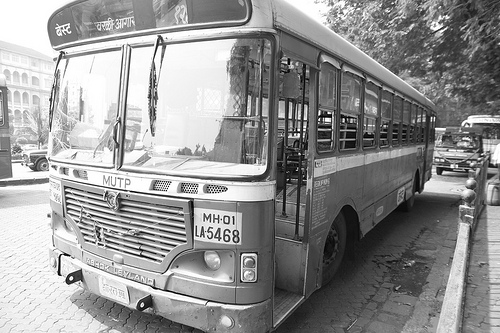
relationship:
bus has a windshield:
[48, 0, 435, 331] [46, 32, 278, 179]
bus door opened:
[44, 0, 435, 333] [269, 95, 313, 216]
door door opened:
[269, 43, 321, 326] [269, 95, 313, 216]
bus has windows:
[48, 0, 435, 331] [317, 50, 424, 146]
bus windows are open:
[48, 0, 435, 331] [279, 60, 310, 260]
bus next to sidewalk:
[48, 0, 435, 331] [409, 192, 478, 321]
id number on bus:
[193, 208, 242, 246] [48, 0, 435, 331]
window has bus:
[337, 58, 360, 158] [48, 0, 435, 331]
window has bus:
[310, 50, 335, 157] [48, 0, 435, 331]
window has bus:
[360, 67, 381, 153] [48, 0, 435, 331]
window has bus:
[380, 82, 393, 152] [48, 0, 435, 331]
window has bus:
[392, 87, 402, 149] [48, 0, 435, 331]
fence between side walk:
[454, 146, 483, 236] [408, 102, 499, 331]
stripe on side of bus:
[304, 138, 433, 177] [161, 25, 393, 302]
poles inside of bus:
[280, 97, 302, 246] [116, 13, 454, 233]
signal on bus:
[235, 246, 262, 291] [48, 0, 435, 331]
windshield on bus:
[50, 37, 270, 169] [22, 6, 467, 331]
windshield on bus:
[48, 36, 273, 177] [48, 0, 435, 331]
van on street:
[433, 127, 484, 177] [3, 161, 479, 331]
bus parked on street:
[48, 0, 435, 331] [3, 161, 479, 331]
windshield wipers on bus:
[147, 35, 163, 136] [48, 0, 435, 331]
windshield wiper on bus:
[48, 52, 68, 134] [48, 0, 435, 331]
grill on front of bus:
[56, 176, 214, 281] [48, 0, 435, 331]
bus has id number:
[48, 0, 435, 331] [192, 207, 241, 244]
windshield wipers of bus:
[24, 47, 190, 137] [8, 0, 454, 320]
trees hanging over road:
[330, 4, 499, 117] [3, 166, 455, 331]